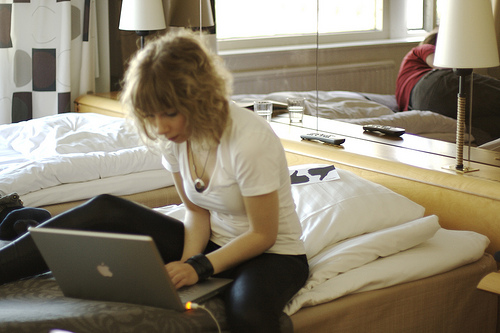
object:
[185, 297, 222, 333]
power cord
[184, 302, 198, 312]
yellow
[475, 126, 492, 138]
ground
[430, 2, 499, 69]
shade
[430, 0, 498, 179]
lamp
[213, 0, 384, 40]
window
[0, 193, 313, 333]
black pants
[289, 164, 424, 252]
pillow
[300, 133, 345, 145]
remote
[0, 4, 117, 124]
curtain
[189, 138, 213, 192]
necklace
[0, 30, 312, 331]
girl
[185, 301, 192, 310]
light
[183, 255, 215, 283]
leather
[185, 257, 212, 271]
wrist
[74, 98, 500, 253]
wooden ledge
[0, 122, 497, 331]
bed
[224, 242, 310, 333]
leg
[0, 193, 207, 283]
leg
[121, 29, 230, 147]
curly hair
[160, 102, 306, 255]
shirt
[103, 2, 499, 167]
mirror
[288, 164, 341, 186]
brochure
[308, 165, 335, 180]
hand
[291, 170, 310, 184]
hand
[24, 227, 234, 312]
computer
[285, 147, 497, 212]
ledge